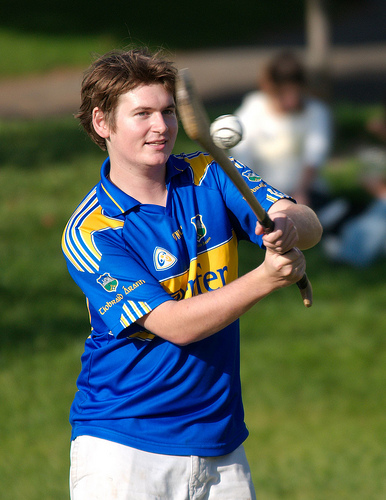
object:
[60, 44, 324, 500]
boy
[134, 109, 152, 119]
eyes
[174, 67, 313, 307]
mallet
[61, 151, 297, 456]
jersey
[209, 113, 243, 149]
ball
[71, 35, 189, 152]
hair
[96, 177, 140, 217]
floor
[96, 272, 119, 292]
emblem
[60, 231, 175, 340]
sleeve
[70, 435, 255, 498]
pants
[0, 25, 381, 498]
grass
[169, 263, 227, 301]
lettering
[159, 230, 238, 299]
background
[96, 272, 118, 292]
patch